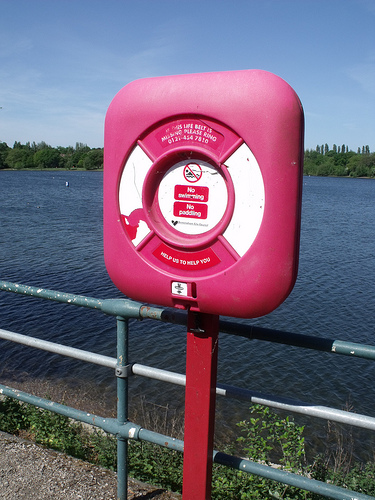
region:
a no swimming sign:
[102, 68, 300, 316]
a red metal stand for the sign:
[180, 321, 210, 492]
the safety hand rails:
[0, 310, 372, 494]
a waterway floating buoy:
[62, 178, 68, 186]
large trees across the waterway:
[305, 143, 374, 177]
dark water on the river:
[303, 175, 374, 333]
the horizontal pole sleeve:
[100, 297, 140, 317]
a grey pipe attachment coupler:
[113, 362, 133, 377]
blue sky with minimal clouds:
[0, 1, 374, 69]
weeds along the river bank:
[1, 395, 182, 491]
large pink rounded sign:
[95, 80, 306, 317]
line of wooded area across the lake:
[7, 133, 369, 181]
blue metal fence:
[11, 269, 362, 489]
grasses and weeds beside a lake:
[18, 361, 351, 491]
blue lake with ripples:
[6, 175, 368, 430]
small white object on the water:
[58, 175, 75, 188]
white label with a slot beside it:
[169, 273, 203, 312]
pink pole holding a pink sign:
[166, 312, 221, 494]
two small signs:
[175, 182, 207, 218]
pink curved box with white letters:
[155, 242, 221, 270]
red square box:
[92, 66, 303, 318]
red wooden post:
[148, 318, 229, 498]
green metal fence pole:
[90, 301, 151, 496]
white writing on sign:
[139, 116, 224, 163]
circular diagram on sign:
[109, 102, 270, 287]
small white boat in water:
[64, 174, 81, 192]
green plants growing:
[218, 412, 293, 498]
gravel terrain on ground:
[0, 444, 62, 498]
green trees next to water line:
[0, 128, 90, 179]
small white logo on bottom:
[159, 280, 195, 299]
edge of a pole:
[243, 453, 253, 473]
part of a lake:
[241, 418, 257, 459]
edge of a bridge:
[52, 428, 58, 451]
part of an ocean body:
[278, 420, 282, 429]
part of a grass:
[87, 391, 97, 399]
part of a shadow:
[275, 331, 281, 343]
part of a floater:
[195, 310, 206, 332]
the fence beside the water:
[1, 275, 371, 496]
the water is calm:
[12, 177, 64, 252]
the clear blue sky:
[12, 7, 98, 41]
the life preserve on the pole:
[90, 71, 303, 320]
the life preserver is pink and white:
[95, 72, 301, 317]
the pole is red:
[177, 316, 230, 496]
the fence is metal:
[2, 277, 373, 484]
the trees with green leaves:
[3, 146, 104, 167]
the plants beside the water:
[31, 420, 121, 463]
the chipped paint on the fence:
[21, 284, 93, 309]